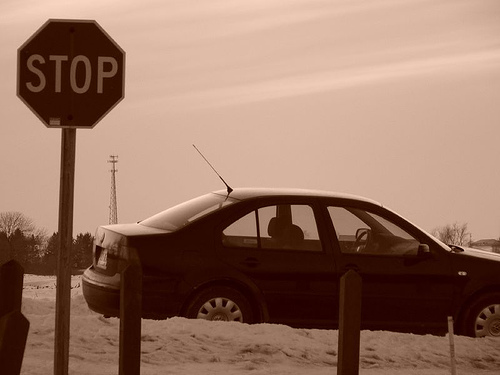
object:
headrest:
[267, 217, 290, 237]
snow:
[0, 269, 500, 375]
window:
[223, 203, 322, 250]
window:
[327, 204, 429, 256]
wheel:
[181, 284, 257, 335]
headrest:
[277, 224, 304, 242]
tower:
[102, 151, 123, 223]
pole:
[49, 127, 78, 372]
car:
[80, 187, 499, 341]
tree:
[427, 220, 474, 248]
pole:
[333, 268, 364, 375]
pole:
[116, 261, 143, 372]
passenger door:
[321, 200, 455, 324]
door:
[214, 197, 340, 321]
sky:
[0, 1, 496, 242]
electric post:
[107, 151, 122, 226]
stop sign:
[15, 17, 126, 131]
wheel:
[457, 292, 498, 337]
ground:
[0, 272, 497, 375]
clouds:
[0, 0, 500, 241]